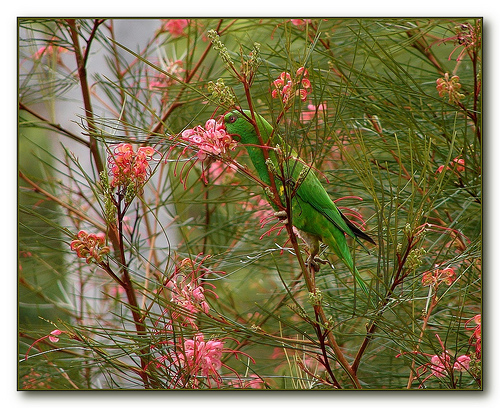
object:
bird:
[215, 108, 377, 313]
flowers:
[142, 328, 254, 386]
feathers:
[293, 178, 370, 255]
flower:
[100, 140, 152, 197]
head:
[217, 106, 254, 142]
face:
[207, 109, 252, 143]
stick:
[65, 20, 104, 174]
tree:
[69, 28, 482, 391]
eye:
[226, 113, 238, 122]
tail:
[321, 225, 384, 309]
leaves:
[250, 298, 355, 387]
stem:
[19, 171, 107, 234]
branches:
[69, 229, 126, 289]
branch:
[293, 355, 337, 387]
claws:
[304, 259, 318, 272]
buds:
[205, 28, 234, 67]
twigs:
[104, 35, 249, 123]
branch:
[205, 77, 252, 123]